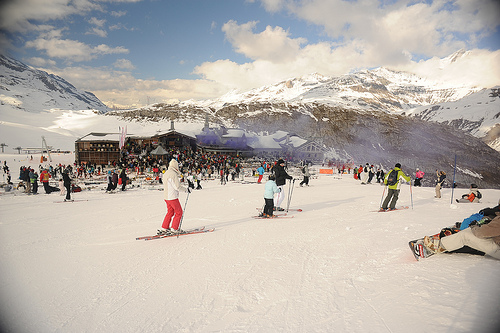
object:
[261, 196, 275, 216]
pants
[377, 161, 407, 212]
person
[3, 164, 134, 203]
people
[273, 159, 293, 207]
person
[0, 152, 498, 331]
ground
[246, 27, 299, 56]
clouds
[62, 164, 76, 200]
skier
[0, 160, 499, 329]
snow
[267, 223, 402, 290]
snow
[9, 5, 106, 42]
white clouds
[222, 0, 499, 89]
clouds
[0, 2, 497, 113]
sky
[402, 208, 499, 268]
skateboarder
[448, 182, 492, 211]
skateboarder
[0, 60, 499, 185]
snow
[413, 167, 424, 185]
skier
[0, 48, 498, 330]
snow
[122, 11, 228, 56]
sky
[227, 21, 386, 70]
white clouds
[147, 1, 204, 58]
blue sky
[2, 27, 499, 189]
mountain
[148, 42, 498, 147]
snow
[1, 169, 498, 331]
slope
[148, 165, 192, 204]
jacket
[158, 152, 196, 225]
person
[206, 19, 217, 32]
cloud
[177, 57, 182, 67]
cloud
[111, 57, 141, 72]
cloud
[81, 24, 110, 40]
cloud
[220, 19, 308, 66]
cloud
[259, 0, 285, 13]
cloud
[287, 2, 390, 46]
cloud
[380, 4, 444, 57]
cloud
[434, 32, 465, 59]
cloud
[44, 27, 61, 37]
cloud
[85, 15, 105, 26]
cloud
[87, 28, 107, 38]
cloud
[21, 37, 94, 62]
cloud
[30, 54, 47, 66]
cloud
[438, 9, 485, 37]
cloud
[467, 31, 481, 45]
cloud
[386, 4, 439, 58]
cloud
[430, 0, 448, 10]
cloud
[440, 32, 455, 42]
cloud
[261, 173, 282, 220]
person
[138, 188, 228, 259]
hillside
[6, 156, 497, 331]
hillside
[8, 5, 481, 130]
sky